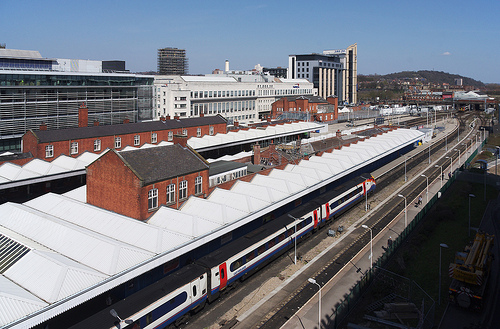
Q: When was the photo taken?
A: Daytime.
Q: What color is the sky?
A: Blue.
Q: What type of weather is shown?
A: Clear.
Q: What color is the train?
A: White and blue.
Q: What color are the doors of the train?
A: Red.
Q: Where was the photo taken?
A: At a train station.